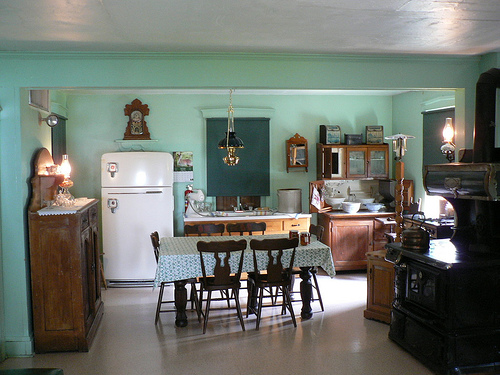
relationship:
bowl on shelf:
[341, 201, 362, 216] [320, 200, 407, 218]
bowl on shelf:
[365, 201, 380, 211] [320, 200, 407, 218]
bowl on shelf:
[322, 197, 346, 209] [320, 200, 407, 218]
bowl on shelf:
[358, 196, 373, 208] [320, 200, 407, 218]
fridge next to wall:
[97, 150, 173, 289] [50, 83, 412, 210]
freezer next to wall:
[99, 150, 173, 189] [50, 83, 412, 210]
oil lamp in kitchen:
[440, 118, 455, 154] [0, 3, 500, 373]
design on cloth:
[155, 237, 331, 287] [151, 232, 337, 293]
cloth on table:
[151, 232, 337, 293] [156, 232, 331, 320]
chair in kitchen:
[246, 237, 298, 331] [0, 3, 500, 373]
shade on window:
[205, 120, 269, 197] [204, 108, 270, 212]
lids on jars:
[291, 223, 305, 234] [287, 227, 312, 246]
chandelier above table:
[217, 106, 245, 167] [155, 236, 330, 325]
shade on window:
[205, 116, 269, 196] [209, 120, 266, 211]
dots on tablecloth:
[155, 235, 334, 289] [155, 232, 336, 282]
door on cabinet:
[323, 146, 330, 177] [316, 142, 347, 180]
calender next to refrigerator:
[170, 145, 200, 191] [91, 140, 183, 290]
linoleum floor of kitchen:
[1, 270, 438, 374] [21, 88, 464, 355]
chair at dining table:
[196, 240, 247, 335] [155, 235, 336, 320]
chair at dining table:
[246, 237, 298, 329] [155, 235, 336, 320]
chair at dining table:
[151, 233, 206, 326] [155, 235, 336, 320]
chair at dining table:
[183, 224, 225, 299] [155, 235, 336, 320]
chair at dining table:
[226, 221, 266, 297] [155, 235, 336, 320]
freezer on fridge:
[99, 150, 173, 189] [97, 150, 173, 289]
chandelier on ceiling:
[217, 106, 245, 167] [1, 2, 499, 94]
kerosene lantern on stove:
[393, 221, 425, 245] [382, 162, 497, 370]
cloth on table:
[153, 232, 342, 283] [155, 236, 330, 325]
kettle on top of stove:
[399, 210, 430, 250] [386, 233, 498, 267]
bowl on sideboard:
[324, 197, 347, 209] [280, 117, 410, 284]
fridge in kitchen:
[84, 159, 206, 292] [0, 3, 500, 373]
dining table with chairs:
[152, 233, 337, 327] [150, 220, 335, 338]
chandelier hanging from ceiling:
[215, 87, 249, 168] [17, 79, 466, 102]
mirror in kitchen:
[284, 137, 309, 172] [20, 88, 498, 365]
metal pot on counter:
[275, 184, 302, 213] [183, 207, 312, 221]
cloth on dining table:
[151, 232, 337, 293] [152, 233, 337, 327]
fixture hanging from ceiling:
[209, 100, 249, 170] [3, 50, 472, 93]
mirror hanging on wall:
[283, 127, 310, 172] [64, 91, 399, 252]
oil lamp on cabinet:
[58, 151, 75, 204] [26, 198, 105, 352]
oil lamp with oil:
[58, 151, 75, 204] [58, 177, 75, 188]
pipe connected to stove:
[457, 54, 497, 121] [393, 159, 499, 358]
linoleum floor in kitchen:
[1, 270, 438, 374] [0, 3, 500, 373]